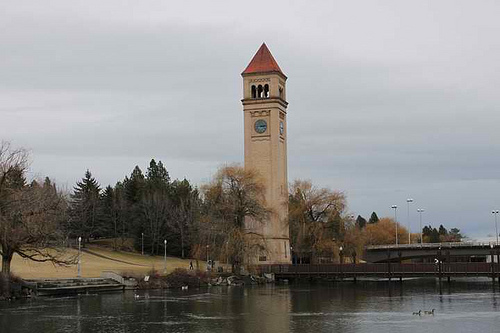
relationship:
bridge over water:
[257, 237, 498, 278] [1, 270, 498, 332]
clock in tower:
[241, 110, 273, 140] [240, 44, 295, 266]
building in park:
[238, 37, 298, 280] [5, 186, 341, 287]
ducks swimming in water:
[388, 287, 469, 329] [268, 266, 499, 326]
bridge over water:
[247, 262, 500, 278] [6, 280, 497, 331]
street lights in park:
[386, 197, 434, 256] [49, 180, 498, 293]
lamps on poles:
[378, 193, 437, 218] [388, 196, 435, 246]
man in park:
[187, 260, 194, 271] [0, 240, 234, 282]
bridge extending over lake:
[247, 262, 500, 278] [14, 277, 498, 331]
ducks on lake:
[408, 306, 435, 316] [39, 294, 483, 331]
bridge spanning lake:
[367, 249, 498, 276] [30, 282, 491, 332]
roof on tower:
[240, 39, 290, 79] [238, 41, 290, 280]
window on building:
[262, 81, 270, 101] [239, 41, 292, 263]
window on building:
[257, 83, 263, 99] [239, 41, 292, 263]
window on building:
[249, 84, 257, 99] [239, 41, 292, 263]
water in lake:
[11, 265, 452, 331] [56, 262, 480, 318]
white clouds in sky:
[30, 40, 73, 103] [4, 0, 466, 181]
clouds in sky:
[7, 70, 96, 146] [3, 29, 238, 149]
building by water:
[239, 41, 292, 263] [1, 270, 498, 332]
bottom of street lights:
[393, 230, 399, 243] [391, 205, 398, 209]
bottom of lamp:
[393, 230, 399, 243] [405, 195, 414, 202]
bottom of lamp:
[393, 230, 399, 243] [418, 207, 424, 209]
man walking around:
[189, 261, 193, 270] [309, 232, 494, 325]